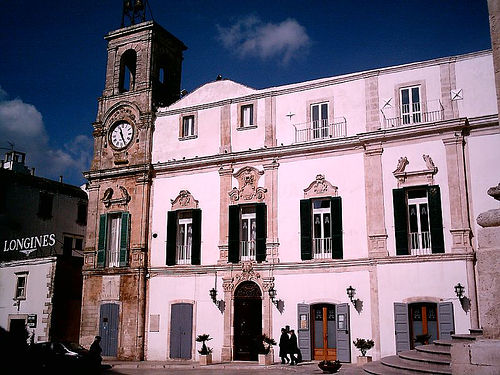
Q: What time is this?
A: 11:25 am.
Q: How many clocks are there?
A: One.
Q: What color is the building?
A: Lavender.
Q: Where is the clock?
A: Tower.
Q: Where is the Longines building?
A: On the left.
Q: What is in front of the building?
A: Plants.